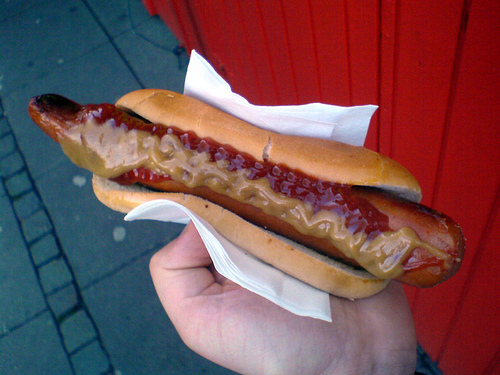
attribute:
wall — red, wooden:
[152, 2, 497, 372]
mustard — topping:
[59, 125, 418, 275]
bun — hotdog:
[114, 78, 421, 198]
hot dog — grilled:
[61, 96, 368, 278]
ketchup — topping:
[59, 97, 394, 232]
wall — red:
[232, 4, 492, 138]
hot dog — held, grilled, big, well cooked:
[26, 88, 466, 303]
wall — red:
[220, 14, 497, 178]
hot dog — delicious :
[146, 144, 404, 261]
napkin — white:
[122, 50, 378, 324]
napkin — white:
[193, 219, 276, 289]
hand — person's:
[142, 206, 424, 374]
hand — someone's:
[129, 213, 437, 373]